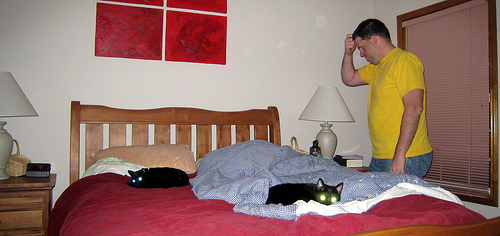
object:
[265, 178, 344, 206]
cat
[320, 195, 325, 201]
eye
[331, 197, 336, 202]
eye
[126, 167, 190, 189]
cat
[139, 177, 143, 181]
eye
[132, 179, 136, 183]
eye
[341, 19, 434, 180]
man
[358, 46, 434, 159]
shirt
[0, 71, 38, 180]
lamp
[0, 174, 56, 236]
table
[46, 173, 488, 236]
blanket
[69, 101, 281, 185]
headboard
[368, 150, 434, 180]
jeans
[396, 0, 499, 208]
window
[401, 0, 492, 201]
blinds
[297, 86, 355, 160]
lamp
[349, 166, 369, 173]
table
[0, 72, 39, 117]
shade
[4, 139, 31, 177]
basket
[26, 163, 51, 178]
alarm clock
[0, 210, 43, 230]
drawer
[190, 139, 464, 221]
blanket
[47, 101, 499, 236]
bed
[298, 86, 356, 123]
shade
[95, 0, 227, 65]
artwork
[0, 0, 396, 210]
wall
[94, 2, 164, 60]
section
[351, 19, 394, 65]
head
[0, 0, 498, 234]
house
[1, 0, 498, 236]
bedroom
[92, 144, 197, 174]
pillow